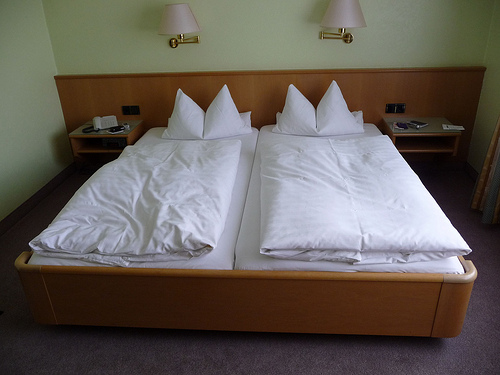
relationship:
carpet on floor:
[1, 160, 497, 374] [5, 156, 499, 372]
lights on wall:
[156, 1, 367, 49] [1, 1, 500, 222]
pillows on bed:
[162, 79, 366, 141] [15, 124, 477, 339]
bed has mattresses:
[15, 124, 477, 339] [28, 123, 467, 273]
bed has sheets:
[15, 124, 477, 339] [28, 122, 469, 274]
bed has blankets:
[15, 124, 477, 339] [29, 135, 473, 267]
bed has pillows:
[15, 124, 477, 339] [162, 79, 366, 141]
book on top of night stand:
[405, 117, 428, 129] [383, 115, 464, 157]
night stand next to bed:
[67, 118, 147, 171] [15, 124, 477, 339]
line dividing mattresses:
[231, 126, 261, 270] [28, 123, 467, 273]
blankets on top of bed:
[29, 135, 473, 267] [15, 124, 477, 339]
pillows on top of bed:
[162, 79, 366, 141] [15, 124, 477, 339]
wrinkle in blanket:
[48, 146, 214, 247] [29, 137, 243, 268]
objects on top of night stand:
[82, 114, 132, 136] [67, 118, 147, 171]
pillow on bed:
[162, 83, 253, 143] [15, 124, 477, 339]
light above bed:
[157, 3, 203, 49] [15, 124, 477, 339]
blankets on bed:
[29, 135, 473, 267] [15, 124, 477, 339]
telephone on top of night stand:
[90, 112, 119, 130] [67, 118, 147, 171]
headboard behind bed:
[52, 65, 486, 165] [15, 124, 477, 339]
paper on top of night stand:
[440, 122, 466, 131] [383, 115, 464, 157]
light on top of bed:
[157, 3, 203, 49] [15, 124, 477, 339]